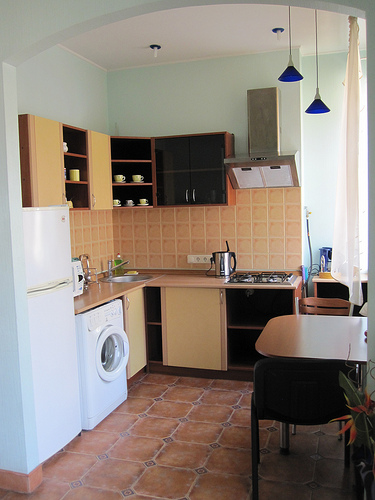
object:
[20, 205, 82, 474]
refrigerator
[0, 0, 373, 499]
kitchen.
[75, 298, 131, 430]
dishwasher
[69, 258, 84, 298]
microwave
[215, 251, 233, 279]
silver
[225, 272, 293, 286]
silver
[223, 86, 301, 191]
vents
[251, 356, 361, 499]
chair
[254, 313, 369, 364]
table.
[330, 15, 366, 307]
curtains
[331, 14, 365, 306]
windows.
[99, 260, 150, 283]
sink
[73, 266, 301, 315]
counter.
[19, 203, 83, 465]
two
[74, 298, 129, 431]
white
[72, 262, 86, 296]
white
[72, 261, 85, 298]
panel.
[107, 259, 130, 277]
faucet.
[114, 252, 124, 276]
bright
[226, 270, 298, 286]
burners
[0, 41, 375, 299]
wall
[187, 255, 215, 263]
outlet.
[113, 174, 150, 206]
saucers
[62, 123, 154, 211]
shelves.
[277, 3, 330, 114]
blue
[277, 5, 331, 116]
hanging.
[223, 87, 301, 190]
silver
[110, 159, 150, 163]
brown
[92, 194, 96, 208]
shelf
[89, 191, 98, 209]
handles.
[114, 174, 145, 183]
teacups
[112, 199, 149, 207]
teacups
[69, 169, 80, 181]
mug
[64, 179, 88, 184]
shelf.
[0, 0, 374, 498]
scene.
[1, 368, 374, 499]
brown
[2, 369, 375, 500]
tiles.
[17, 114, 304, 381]
brown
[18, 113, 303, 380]
cabinet.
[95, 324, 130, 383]
door.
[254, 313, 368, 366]
top.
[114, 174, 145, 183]
yellow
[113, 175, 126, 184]
mugs.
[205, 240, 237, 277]
kettle.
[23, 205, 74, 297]
freezer.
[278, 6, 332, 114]
fixture.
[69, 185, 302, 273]
tan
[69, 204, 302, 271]
backsplash.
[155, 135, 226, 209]
cupboard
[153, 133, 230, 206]
glass.